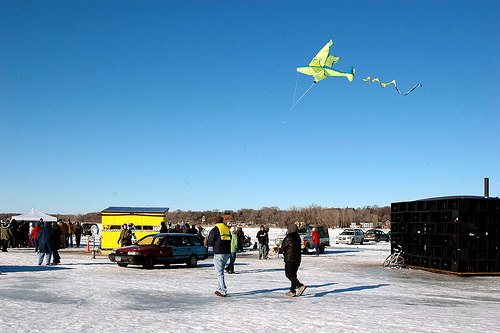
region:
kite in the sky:
[287, 31, 429, 108]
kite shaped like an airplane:
[284, 36, 440, 116]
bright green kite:
[292, 31, 422, 116]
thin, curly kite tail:
[354, 66, 436, 103]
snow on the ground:
[0, 242, 497, 332]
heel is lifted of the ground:
[297, 281, 309, 301]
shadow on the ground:
[309, 279, 391, 298]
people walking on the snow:
[3, 213, 346, 310]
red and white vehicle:
[99, 228, 210, 275]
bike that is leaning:
[378, 240, 410, 272]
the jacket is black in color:
[274, 235, 310, 262]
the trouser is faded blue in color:
[215, 258, 229, 292]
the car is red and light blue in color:
[123, 225, 193, 277]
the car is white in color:
[336, 223, 363, 243]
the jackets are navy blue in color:
[38, 227, 64, 252]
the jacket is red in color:
[308, 227, 320, 243]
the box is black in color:
[416, 199, 468, 253]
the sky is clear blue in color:
[204, 111, 264, 141]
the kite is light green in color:
[296, 45, 366, 93]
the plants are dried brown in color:
[322, 200, 349, 221]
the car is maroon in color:
[140, 235, 189, 265]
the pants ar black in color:
[286, 257, 313, 287]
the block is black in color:
[430, 222, 477, 265]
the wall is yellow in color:
[103, 220, 118, 245]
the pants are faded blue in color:
[211, 250, 248, 286]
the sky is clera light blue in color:
[117, 103, 169, 173]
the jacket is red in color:
[307, 223, 332, 246]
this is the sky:
[51, 31, 211, 133]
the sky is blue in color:
[92, 15, 180, 83]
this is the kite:
[299, 44, 362, 84]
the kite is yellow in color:
[304, 60, 332, 75]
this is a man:
[210, 208, 236, 302]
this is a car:
[337, 220, 369, 241]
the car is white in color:
[340, 235, 356, 240]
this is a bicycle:
[372, 246, 405, 267]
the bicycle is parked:
[383, 244, 407, 268]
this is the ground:
[104, 264, 175, 324]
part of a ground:
[340, 288, 368, 327]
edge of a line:
[448, 264, 466, 289]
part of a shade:
[340, 286, 360, 311]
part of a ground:
[330, 268, 347, 283]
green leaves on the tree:
[322, 201, 336, 224]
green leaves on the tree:
[344, 207, 354, 224]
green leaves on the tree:
[322, 214, 342, 232]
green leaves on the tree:
[299, 196, 326, 235]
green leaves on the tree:
[263, 201, 288, 240]